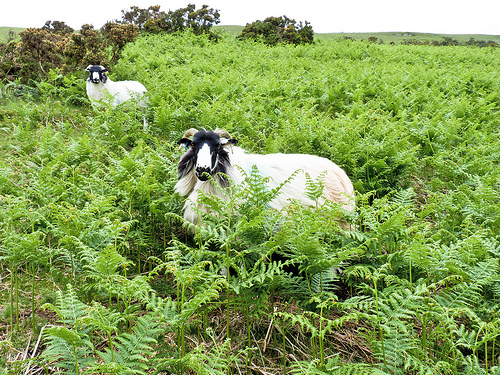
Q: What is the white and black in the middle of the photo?
A: Goat.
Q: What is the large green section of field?
A: Fern plants.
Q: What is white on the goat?
A: Fur.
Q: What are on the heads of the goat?
A: Horns.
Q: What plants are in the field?
A: Ferns.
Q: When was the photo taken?
A: During the daytime.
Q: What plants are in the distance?
A: Bushes.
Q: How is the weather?
A: Cloudy.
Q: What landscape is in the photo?
A: Grassland.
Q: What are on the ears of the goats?
A: Tags.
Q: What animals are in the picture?
A: Goats.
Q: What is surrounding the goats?
A: Ferns.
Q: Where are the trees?
A: Behind the goats.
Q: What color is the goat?
A: White and black.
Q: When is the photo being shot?
A: Daytime.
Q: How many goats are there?
A: 2.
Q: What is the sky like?
A: Clear.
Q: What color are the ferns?
A: Green.